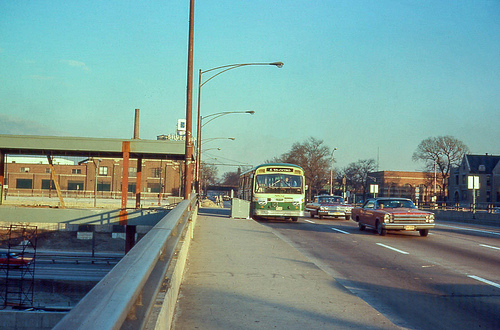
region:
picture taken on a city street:
[7, 20, 499, 321]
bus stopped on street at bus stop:
[225, 153, 312, 225]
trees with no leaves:
[300, 121, 477, 181]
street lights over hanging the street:
[188, 50, 291, 205]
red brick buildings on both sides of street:
[8, 152, 441, 192]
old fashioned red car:
[347, 184, 443, 241]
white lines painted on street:
[390, 222, 499, 315]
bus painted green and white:
[245, 153, 312, 223]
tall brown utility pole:
[165, 2, 215, 205]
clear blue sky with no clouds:
[285, 24, 448, 134]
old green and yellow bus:
[237, 162, 305, 215]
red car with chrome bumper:
[350, 197, 435, 231]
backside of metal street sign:
[467, 175, 480, 212]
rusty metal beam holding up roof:
[120, 139, 130, 219]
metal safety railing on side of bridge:
[162, 198, 189, 247]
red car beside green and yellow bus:
[306, 194, 351, 212]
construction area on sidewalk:
[197, 196, 219, 209]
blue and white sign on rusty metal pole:
[178, 118, 190, 133]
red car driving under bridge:
[1, 252, 33, 271]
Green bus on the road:
[231, 154, 315, 227]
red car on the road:
[346, 173, 434, 233]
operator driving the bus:
[278, 169, 300, 194]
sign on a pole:
[466, 170, 483, 196]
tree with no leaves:
[405, 126, 475, 176]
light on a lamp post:
[258, 57, 287, 74]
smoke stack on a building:
[131, 104, 144, 136]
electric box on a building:
[173, 106, 193, 143]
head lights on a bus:
[256, 195, 306, 205]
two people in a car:
[374, 189, 406, 211]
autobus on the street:
[242, 153, 311, 227]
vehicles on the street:
[311, 188, 443, 239]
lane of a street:
[341, 252, 397, 286]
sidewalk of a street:
[204, 259, 291, 328]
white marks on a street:
[368, 236, 420, 261]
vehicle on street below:
[1, 246, 37, 273]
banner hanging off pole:
[177, 117, 197, 137]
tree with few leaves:
[413, 125, 470, 202]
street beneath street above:
[0, 250, 108, 275]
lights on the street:
[197, 55, 293, 143]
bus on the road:
[250, 159, 311, 221]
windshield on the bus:
[251, 171, 303, 195]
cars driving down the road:
[307, 187, 435, 249]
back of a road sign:
[463, 171, 483, 206]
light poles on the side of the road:
[192, 54, 287, 195]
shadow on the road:
[349, 270, 475, 329]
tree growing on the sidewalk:
[412, 127, 474, 214]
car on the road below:
[1, 244, 33, 268]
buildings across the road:
[448, 156, 493, 211]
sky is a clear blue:
[309, 30, 428, 84]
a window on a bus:
[257, 173, 300, 190]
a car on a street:
[309, 191, 355, 224]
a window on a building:
[481, 190, 491, 198]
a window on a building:
[448, 171, 458, 181]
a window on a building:
[459, 173, 462, 180]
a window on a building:
[71, 166, 73, 171]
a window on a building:
[76, 165, 81, 174]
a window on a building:
[92, 165, 112, 175]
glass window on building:
[14, 177, 34, 190]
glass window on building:
[42, 178, 56, 188]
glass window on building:
[66, 180, 84, 190]